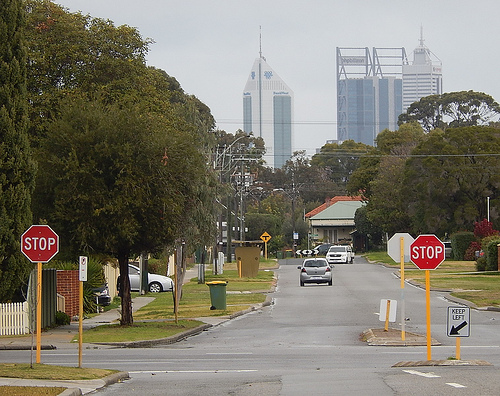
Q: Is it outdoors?
A: Yes, it is outdoors.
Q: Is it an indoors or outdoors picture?
A: It is outdoors.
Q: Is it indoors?
A: No, it is outdoors.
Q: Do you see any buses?
A: No, there are no buses.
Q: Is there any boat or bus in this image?
A: No, there are no buses or boats.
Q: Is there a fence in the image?
A: Yes, there is a fence.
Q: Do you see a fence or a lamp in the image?
A: Yes, there is a fence.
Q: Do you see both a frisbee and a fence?
A: No, there is a fence but no frisbees.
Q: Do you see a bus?
A: No, there are no buses.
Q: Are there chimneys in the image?
A: No, there are no chimneys.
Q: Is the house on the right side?
A: Yes, the house is on the right of the image.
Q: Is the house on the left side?
A: No, the house is on the right of the image.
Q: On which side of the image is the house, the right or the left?
A: The house is on the right of the image.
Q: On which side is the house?
A: The house is on the right of the image.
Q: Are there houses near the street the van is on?
A: Yes, there is a house near the street.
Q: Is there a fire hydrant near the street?
A: No, there is a house near the street.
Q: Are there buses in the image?
A: No, there are no buses.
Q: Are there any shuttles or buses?
A: No, there are no buses or shuttles.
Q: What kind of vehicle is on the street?
A: The vehicle is a van.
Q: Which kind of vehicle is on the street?
A: The vehicle is a van.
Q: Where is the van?
A: The van is on the street.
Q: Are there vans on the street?
A: Yes, there is a van on the street.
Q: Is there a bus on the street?
A: No, there is a van on the street.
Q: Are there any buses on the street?
A: No, there is a van on the street.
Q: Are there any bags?
A: No, there are no bags.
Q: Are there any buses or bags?
A: No, there are no bags or buses.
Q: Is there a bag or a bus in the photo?
A: No, there are no bags or buses.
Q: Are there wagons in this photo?
A: No, there are no wagons.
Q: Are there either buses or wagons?
A: No, there are no wagons or buses.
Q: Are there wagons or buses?
A: No, there are no wagons or buses.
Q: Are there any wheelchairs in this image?
A: No, there are no wheelchairs.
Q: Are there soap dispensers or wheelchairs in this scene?
A: No, there are no wheelchairs or soap dispensers.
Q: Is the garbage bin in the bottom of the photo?
A: Yes, the garbage bin is in the bottom of the image.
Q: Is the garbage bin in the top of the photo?
A: No, the garbage bin is in the bottom of the image.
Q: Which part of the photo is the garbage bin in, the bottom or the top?
A: The garbage bin is in the bottom of the image.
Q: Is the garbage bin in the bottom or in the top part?
A: The garbage bin is in the bottom of the image.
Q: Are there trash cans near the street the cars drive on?
A: Yes, there is a trash can near the street.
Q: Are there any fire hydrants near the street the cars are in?
A: No, there is a trash can near the street.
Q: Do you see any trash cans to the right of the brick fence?
A: Yes, there is a trash can to the right of the fence.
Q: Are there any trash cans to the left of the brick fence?
A: No, the trash can is to the right of the fence.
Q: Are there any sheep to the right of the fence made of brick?
A: No, there is a trash can to the right of the fence.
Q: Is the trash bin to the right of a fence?
A: Yes, the trash bin is to the right of a fence.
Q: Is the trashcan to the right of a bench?
A: No, the trashcan is to the right of a fence.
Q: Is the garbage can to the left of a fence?
A: No, the garbage can is to the right of a fence.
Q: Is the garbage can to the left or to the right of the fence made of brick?
A: The garbage can is to the right of the fence.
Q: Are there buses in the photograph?
A: No, there are no buses.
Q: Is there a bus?
A: No, there are no buses.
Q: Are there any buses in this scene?
A: No, there are no buses.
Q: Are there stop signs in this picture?
A: Yes, there is a stop sign.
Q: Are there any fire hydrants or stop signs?
A: Yes, there is a stop sign.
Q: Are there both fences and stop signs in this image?
A: Yes, there are both a stop sign and a fence.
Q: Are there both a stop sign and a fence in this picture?
A: Yes, there are both a stop sign and a fence.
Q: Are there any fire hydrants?
A: No, there are no fire hydrants.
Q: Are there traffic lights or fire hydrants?
A: No, there are no fire hydrants or traffic lights.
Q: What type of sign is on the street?
A: The sign is a stop sign.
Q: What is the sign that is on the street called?
A: The sign is a stop sign.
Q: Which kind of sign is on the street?
A: The sign is a stop sign.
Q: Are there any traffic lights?
A: No, there are no traffic lights.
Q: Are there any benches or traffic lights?
A: No, there are no traffic lights or benches.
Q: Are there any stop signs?
A: Yes, there is a stop sign.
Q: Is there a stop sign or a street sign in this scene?
A: Yes, there is a stop sign.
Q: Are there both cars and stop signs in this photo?
A: Yes, there are both a stop sign and a car.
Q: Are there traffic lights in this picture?
A: No, there are no traffic lights.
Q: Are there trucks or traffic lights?
A: No, there are no traffic lights or trucks.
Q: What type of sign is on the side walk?
A: The sign is a stop sign.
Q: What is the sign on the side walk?
A: The sign is a stop sign.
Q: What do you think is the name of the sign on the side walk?
A: The sign is a stop sign.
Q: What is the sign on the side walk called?
A: The sign is a stop sign.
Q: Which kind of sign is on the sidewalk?
A: The sign is a stop sign.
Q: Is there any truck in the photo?
A: No, there are no trucks.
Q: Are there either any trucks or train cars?
A: No, there are no trucks or train cars.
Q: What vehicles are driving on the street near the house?
A: The vehicles are cars.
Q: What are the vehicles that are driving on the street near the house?
A: The vehicles are cars.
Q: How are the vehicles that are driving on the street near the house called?
A: The vehicles are cars.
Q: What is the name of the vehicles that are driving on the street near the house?
A: The vehicles are cars.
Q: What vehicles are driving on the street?
A: The vehicles are cars.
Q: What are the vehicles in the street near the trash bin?
A: The vehicles are cars.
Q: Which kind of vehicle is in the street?
A: The vehicles are cars.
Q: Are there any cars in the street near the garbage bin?
A: Yes, there are cars in the street.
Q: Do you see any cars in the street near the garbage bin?
A: Yes, there are cars in the street.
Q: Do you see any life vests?
A: No, there are no life vests.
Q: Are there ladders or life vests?
A: No, there are no life vests or ladders.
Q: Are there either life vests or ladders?
A: No, there are no life vests or ladders.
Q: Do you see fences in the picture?
A: Yes, there is a fence.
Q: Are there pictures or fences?
A: Yes, there is a fence.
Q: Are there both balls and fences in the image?
A: No, there is a fence but no balls.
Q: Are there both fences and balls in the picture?
A: No, there is a fence but no balls.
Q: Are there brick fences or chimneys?
A: Yes, there is a brick fence.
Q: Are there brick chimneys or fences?
A: Yes, there is a brick fence.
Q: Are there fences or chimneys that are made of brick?
A: Yes, the fence is made of brick.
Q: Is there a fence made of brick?
A: Yes, there is a fence that is made of brick.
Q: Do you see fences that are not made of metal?
A: Yes, there is a fence that is made of brick.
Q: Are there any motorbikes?
A: No, there are no motorbikes.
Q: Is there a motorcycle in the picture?
A: No, there are no motorcycles.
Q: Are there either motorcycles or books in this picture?
A: No, there are no motorcycles or books.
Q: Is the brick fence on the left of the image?
A: Yes, the fence is on the left of the image.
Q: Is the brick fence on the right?
A: No, the fence is on the left of the image.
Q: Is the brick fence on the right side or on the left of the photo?
A: The fence is on the left of the image.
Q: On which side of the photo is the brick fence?
A: The fence is on the left of the image.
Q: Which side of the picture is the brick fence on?
A: The fence is on the left of the image.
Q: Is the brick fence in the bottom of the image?
A: Yes, the fence is in the bottom of the image.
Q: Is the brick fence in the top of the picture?
A: No, the fence is in the bottom of the image.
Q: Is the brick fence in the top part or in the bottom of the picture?
A: The fence is in the bottom of the image.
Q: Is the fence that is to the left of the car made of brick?
A: Yes, the fence is made of brick.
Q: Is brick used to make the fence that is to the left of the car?
A: Yes, the fence is made of brick.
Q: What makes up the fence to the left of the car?
A: The fence is made of brick.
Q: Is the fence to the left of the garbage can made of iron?
A: No, the fence is made of brick.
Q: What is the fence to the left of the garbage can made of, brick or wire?
A: The fence is made of brick.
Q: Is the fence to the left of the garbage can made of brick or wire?
A: The fence is made of brick.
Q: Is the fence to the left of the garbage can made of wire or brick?
A: The fence is made of brick.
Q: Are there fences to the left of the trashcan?
A: Yes, there is a fence to the left of the trashcan.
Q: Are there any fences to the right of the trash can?
A: No, the fence is to the left of the trash can.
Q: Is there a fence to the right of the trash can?
A: No, the fence is to the left of the trash can.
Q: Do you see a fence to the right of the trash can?
A: No, the fence is to the left of the trash can.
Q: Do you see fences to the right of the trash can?
A: No, the fence is to the left of the trash can.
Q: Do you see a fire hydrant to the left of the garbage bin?
A: No, there is a fence to the left of the garbage bin.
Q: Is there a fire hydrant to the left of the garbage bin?
A: No, there is a fence to the left of the garbage bin.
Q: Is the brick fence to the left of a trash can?
A: Yes, the fence is to the left of a trash can.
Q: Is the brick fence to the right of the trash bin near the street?
A: No, the fence is to the left of the trashcan.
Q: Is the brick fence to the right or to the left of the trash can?
A: The fence is to the left of the trash can.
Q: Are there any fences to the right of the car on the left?
A: No, the fence is to the left of the car.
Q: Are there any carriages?
A: No, there are no carriages.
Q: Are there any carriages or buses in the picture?
A: No, there are no carriages or buses.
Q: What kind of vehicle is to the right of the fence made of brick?
A: The vehicle is a car.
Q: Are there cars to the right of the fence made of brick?
A: Yes, there is a car to the right of the fence.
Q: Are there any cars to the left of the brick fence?
A: No, the car is to the right of the fence.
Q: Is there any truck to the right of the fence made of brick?
A: No, there is a car to the right of the fence.